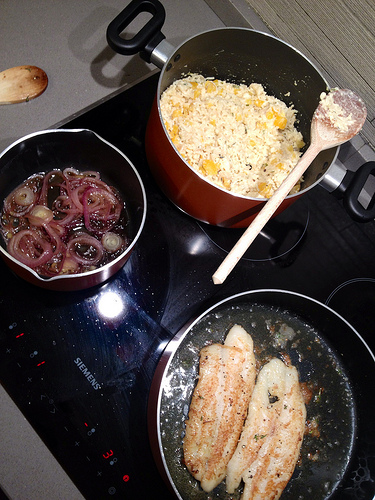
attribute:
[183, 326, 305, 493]
fish —  2,  seasoned ,  oily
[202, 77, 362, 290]
spoon — wood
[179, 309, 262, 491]
fish — fried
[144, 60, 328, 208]
pot — metal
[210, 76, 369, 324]
spoon —  wooden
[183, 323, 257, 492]
cutlet — being fired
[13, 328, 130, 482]
numbers —  lit up,  Red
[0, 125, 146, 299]
red pot —  big ,  red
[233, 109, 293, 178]
herbs —  green, of fish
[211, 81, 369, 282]
spoon —  wooden, wooden, cooking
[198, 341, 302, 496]
cutlets — brown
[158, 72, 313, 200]
rice —  cooked 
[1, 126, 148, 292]
pot —   black,  for cooking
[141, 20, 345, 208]
pot — holding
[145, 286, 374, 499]
skillet —  dark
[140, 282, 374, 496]
pan — full, metal, for frying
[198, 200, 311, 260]
burner —  stove's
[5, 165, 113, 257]
onions —  sauteed 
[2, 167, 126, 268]
onions — Sliced,   fried,  red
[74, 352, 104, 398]
siemens — brand name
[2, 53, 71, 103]
spoon —  wooden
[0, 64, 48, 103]
spoon —  wooden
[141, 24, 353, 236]
pot — red, double-handled, large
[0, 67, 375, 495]
stove top —  Flameless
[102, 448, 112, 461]
number —  3, of range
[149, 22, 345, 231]
pot —  red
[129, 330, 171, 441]
handles — black 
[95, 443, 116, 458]
number — 3 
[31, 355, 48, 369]
number — 1 